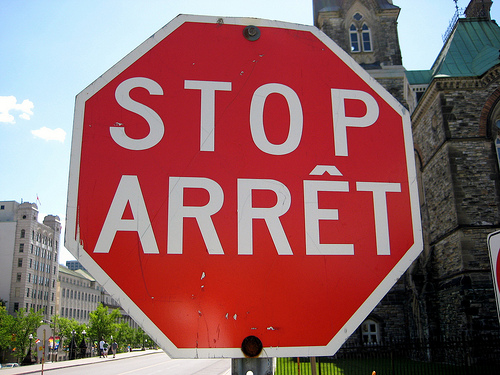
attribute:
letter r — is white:
[235, 178, 292, 256]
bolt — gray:
[234, 334, 269, 359]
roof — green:
[405, 20, 499, 86]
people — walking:
[85, 323, 125, 365]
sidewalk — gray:
[0, 347, 162, 373]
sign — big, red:
[17, 2, 494, 372]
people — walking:
[96, 336, 120, 358]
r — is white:
[165, 174, 225, 259]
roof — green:
[426, 16, 498, 78]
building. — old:
[251, 14, 498, 373]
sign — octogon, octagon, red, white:
[55, 14, 436, 374]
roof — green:
[405, 1, 497, 70]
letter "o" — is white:
[248, 81, 303, 156]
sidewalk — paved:
[6, 339, 161, 364]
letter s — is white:
[105, 72, 168, 157]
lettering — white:
[89, 77, 391, 257]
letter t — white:
[179, 73, 234, 157]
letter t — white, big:
[358, 182, 406, 255]